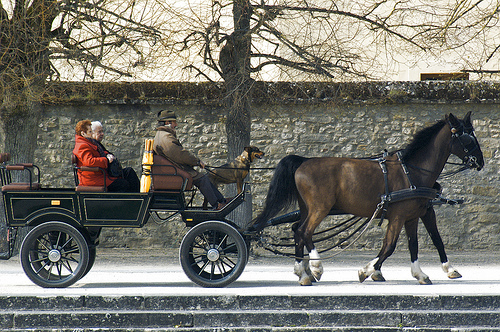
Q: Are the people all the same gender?
A: No, they are both male and female.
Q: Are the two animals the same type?
A: No, they are horses and dogs.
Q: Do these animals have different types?
A: Yes, they are horses and dogs.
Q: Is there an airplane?
A: No, there are no airplanes.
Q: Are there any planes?
A: No, there are no planes.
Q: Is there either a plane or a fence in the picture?
A: No, there are no airplanes or fences.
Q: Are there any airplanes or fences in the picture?
A: No, there are no airplanes or fences.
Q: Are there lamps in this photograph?
A: No, there are no lamps.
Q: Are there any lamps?
A: No, there are no lamps.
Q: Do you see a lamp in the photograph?
A: No, there are no lamps.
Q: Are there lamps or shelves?
A: No, there are no lamps or shelves.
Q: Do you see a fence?
A: No, there are no fences.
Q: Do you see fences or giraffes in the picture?
A: No, there are no fences or giraffes.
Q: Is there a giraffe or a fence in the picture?
A: No, there are no fences or giraffes.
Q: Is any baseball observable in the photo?
A: No, there are no baseballs.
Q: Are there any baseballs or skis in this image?
A: No, there are no baseballs or skis.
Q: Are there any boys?
A: No, there are no boys.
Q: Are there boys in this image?
A: No, there are no boys.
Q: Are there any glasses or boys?
A: No, there are no boys or glasses.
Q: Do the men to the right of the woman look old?
A: Yes, the men are old.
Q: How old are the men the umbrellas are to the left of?
A: The men are old.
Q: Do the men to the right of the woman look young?
A: No, the men are old.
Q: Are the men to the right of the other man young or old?
A: The men are old.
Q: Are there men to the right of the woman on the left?
A: Yes, there are men to the right of the woman.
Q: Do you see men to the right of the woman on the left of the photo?
A: Yes, there are men to the right of the woman.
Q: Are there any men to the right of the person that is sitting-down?
A: Yes, there are men to the right of the woman.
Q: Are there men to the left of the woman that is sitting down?
A: No, the men are to the right of the woman.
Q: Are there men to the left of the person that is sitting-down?
A: No, the men are to the right of the woman.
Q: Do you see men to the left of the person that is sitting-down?
A: No, the men are to the right of the woman.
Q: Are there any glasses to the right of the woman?
A: No, there are men to the right of the woman.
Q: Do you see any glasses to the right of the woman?
A: No, there are men to the right of the woman.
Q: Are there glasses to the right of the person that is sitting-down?
A: No, there are men to the right of the woman.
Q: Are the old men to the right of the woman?
A: Yes, the men are to the right of the woman.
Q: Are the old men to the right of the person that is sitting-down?
A: Yes, the men are to the right of the woman.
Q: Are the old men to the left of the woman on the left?
A: No, the men are to the right of the woman.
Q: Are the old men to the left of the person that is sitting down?
A: No, the men are to the right of the woman.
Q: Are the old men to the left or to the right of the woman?
A: The men are to the right of the woman.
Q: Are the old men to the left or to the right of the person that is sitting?
A: The men are to the right of the woman.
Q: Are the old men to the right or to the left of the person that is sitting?
A: The men are to the right of the woman.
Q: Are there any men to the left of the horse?
A: Yes, there are men to the left of the horse.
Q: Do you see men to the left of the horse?
A: Yes, there are men to the left of the horse.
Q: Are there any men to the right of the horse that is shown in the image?
A: No, the men are to the left of the horse.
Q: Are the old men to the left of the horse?
A: Yes, the men are to the left of the horse.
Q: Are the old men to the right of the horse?
A: No, the men are to the left of the horse.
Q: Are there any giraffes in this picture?
A: No, there are no giraffes.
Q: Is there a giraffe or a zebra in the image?
A: No, there are no giraffes or zebras.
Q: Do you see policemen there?
A: No, there are no policemen.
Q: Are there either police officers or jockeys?
A: No, there are no police officers or jockeys.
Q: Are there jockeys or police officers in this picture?
A: No, there are no police officers or jockeys.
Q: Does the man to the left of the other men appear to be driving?
A: Yes, the man is driving.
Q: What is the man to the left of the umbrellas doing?
A: The man is driving.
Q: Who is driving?
A: The man is driving.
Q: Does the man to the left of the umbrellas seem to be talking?
A: No, the man is driving.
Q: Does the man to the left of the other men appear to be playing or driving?
A: The man is driving.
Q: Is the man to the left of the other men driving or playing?
A: The man is driving.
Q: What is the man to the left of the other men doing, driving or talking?
A: The man is driving.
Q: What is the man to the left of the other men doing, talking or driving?
A: The man is driving.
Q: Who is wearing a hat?
A: The man is wearing a hat.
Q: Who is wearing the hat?
A: The man is wearing a hat.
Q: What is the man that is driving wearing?
A: The man is wearing a hat.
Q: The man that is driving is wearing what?
A: The man is wearing a hat.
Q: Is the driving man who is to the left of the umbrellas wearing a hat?
A: Yes, the man is wearing a hat.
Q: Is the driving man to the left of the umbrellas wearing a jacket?
A: No, the man is wearing a hat.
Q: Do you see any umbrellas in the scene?
A: Yes, there are umbrellas.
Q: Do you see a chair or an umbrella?
A: Yes, there are umbrellas.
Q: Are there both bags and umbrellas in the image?
A: No, there are umbrellas but no bags.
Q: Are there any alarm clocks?
A: No, there are no alarm clocks.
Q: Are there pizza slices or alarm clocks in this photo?
A: No, there are no alarm clocks or pizza slices.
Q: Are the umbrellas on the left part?
A: Yes, the umbrellas are on the left of the image.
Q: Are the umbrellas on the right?
A: No, the umbrellas are on the left of the image.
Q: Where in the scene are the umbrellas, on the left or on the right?
A: The umbrellas are on the left of the image.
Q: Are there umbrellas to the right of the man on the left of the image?
A: Yes, there are umbrellas to the right of the man.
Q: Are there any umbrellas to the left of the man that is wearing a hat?
A: No, the umbrellas are to the right of the man.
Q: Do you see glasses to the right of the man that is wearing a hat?
A: No, there are umbrellas to the right of the man.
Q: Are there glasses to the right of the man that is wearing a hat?
A: No, there are umbrellas to the right of the man.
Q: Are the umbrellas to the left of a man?
A: No, the umbrellas are to the right of a man.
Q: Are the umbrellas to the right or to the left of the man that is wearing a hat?
A: The umbrellas are to the right of the man.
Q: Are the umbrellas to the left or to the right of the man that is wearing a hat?
A: The umbrellas are to the right of the man.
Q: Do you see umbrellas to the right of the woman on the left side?
A: Yes, there are umbrellas to the right of the woman.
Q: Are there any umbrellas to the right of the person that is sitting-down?
A: Yes, there are umbrellas to the right of the woman.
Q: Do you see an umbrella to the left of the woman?
A: No, the umbrellas are to the right of the woman.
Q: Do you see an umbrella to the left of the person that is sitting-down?
A: No, the umbrellas are to the right of the woman.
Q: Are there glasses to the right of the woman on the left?
A: No, there are umbrellas to the right of the woman.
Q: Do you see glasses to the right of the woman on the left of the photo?
A: No, there are umbrellas to the right of the woman.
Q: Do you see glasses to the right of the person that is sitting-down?
A: No, there are umbrellas to the right of the woman.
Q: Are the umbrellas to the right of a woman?
A: Yes, the umbrellas are to the right of a woman.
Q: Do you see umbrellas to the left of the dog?
A: Yes, there are umbrellas to the left of the dog.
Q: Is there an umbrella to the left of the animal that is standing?
A: Yes, there are umbrellas to the left of the dog.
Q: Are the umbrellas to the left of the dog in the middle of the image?
A: Yes, the umbrellas are to the left of the dog.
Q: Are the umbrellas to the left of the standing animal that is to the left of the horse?
A: Yes, the umbrellas are to the left of the dog.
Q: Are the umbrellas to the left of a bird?
A: No, the umbrellas are to the left of the dog.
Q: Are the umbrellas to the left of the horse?
A: Yes, the umbrellas are to the left of the horse.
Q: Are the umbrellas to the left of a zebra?
A: No, the umbrellas are to the left of the horse.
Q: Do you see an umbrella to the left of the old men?
A: Yes, there are umbrellas to the left of the men.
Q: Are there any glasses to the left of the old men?
A: No, there are umbrellas to the left of the men.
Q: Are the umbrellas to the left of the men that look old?
A: Yes, the umbrellas are to the left of the men.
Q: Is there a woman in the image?
A: Yes, there is a woman.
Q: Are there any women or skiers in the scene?
A: Yes, there is a woman.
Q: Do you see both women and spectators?
A: No, there is a woman but no spectators.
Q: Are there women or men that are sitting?
A: Yes, the woman is sitting.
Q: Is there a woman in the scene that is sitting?
A: Yes, there is a woman that is sitting.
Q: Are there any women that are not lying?
A: Yes, there is a woman that is sitting.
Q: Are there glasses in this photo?
A: No, there are no glasses.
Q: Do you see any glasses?
A: No, there are no glasses.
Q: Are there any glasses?
A: No, there are no glasses.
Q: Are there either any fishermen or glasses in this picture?
A: No, there are no glasses or fishermen.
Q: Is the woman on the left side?
A: Yes, the woman is on the left of the image.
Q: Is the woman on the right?
A: No, the woman is on the left of the image.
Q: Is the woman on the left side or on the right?
A: The woman is on the left of the image.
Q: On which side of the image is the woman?
A: The woman is on the left of the image.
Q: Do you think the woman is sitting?
A: Yes, the woman is sitting.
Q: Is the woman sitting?
A: Yes, the woman is sitting.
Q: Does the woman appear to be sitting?
A: Yes, the woman is sitting.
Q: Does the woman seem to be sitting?
A: Yes, the woman is sitting.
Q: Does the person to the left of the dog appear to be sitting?
A: Yes, the woman is sitting.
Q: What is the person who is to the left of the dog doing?
A: The woman is sitting.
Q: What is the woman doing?
A: The woman is sitting.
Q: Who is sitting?
A: The woman is sitting.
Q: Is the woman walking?
A: No, the woman is sitting.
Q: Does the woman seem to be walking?
A: No, the woman is sitting.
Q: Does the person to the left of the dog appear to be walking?
A: No, the woman is sitting.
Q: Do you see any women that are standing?
A: No, there is a woman but she is sitting.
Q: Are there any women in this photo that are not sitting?
A: No, there is a woman but she is sitting.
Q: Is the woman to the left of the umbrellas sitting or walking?
A: The woman is sitting.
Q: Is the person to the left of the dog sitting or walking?
A: The woman is sitting.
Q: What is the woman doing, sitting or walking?
A: The woman is sitting.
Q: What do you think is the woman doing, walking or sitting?
A: The woman is sitting.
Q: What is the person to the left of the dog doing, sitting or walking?
A: The woman is sitting.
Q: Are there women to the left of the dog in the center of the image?
A: Yes, there is a woman to the left of the dog.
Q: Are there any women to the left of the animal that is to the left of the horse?
A: Yes, there is a woman to the left of the dog.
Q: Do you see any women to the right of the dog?
A: No, the woman is to the left of the dog.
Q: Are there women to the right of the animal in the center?
A: No, the woman is to the left of the dog.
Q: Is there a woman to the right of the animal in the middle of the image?
A: No, the woman is to the left of the dog.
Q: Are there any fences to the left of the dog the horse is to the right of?
A: No, there is a woman to the left of the dog.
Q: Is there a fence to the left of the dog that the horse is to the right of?
A: No, there is a woman to the left of the dog.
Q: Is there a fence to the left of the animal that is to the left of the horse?
A: No, there is a woman to the left of the dog.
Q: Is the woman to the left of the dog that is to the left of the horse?
A: Yes, the woman is to the left of the dog.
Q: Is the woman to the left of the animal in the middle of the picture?
A: Yes, the woman is to the left of the dog.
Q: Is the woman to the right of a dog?
A: No, the woman is to the left of a dog.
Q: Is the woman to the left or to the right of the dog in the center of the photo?
A: The woman is to the left of the dog.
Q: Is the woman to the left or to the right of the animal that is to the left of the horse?
A: The woman is to the left of the dog.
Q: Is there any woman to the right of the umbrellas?
A: No, the woman is to the left of the umbrellas.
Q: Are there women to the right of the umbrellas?
A: No, the woman is to the left of the umbrellas.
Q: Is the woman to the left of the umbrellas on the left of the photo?
A: Yes, the woman is to the left of the umbrellas.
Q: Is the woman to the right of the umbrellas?
A: No, the woman is to the left of the umbrellas.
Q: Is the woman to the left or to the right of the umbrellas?
A: The woman is to the left of the umbrellas.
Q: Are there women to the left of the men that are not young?
A: Yes, there is a woman to the left of the men.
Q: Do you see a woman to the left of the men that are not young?
A: Yes, there is a woman to the left of the men.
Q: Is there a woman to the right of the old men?
A: No, the woman is to the left of the men.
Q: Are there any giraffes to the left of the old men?
A: No, there is a woman to the left of the men.